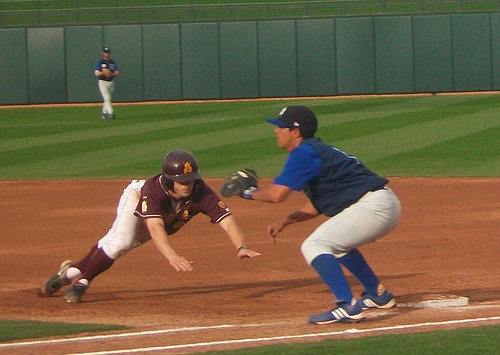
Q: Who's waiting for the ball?
A: The baseman.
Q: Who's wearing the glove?
A: The baseman.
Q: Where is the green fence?
A: Behind the field.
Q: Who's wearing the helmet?
A: The runner.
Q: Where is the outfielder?
A: On the grass.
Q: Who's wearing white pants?
A: All the players.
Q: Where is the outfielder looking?
A: At the baseman and runner.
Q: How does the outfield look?
A: Well trimmed.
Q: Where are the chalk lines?
A: On the dirt.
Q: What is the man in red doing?
A: Diving for a base.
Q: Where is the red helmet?
A: On the man in red and white.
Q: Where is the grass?
A: On the field.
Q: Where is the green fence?
A: Behind outfielder.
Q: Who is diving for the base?
A: Player.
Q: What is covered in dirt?
A: Field.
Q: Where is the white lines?
A: Baseball field.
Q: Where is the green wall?
A: Behind the player.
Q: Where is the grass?
A: Baseball field.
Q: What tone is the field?
A: Green.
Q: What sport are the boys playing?
A: Baseball.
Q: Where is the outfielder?
A: In the grass.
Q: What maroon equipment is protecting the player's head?
A: Helmet.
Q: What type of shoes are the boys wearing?
A: Cleats.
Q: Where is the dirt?
A: On the field.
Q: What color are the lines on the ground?
A: White.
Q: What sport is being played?
A: Baseball.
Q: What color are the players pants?
A: White.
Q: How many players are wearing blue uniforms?
A: 2.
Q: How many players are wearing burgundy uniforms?
A: 1.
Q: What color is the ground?
A: Brown and green.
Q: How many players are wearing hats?
A: 3.